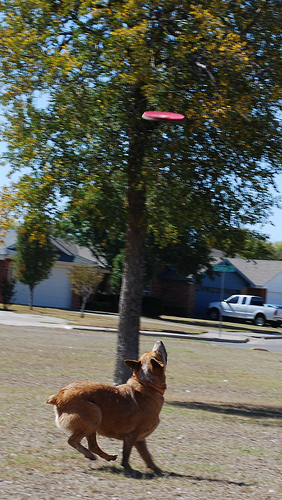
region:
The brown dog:
[42, 336, 168, 475]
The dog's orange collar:
[132, 376, 165, 394]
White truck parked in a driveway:
[209, 292, 280, 327]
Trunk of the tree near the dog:
[109, 91, 145, 391]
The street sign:
[211, 256, 239, 338]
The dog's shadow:
[88, 459, 258, 488]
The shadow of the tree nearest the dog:
[163, 396, 281, 425]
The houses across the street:
[0, 224, 281, 326]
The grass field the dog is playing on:
[1, 323, 281, 499]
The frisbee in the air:
[136, 108, 186, 128]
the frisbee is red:
[120, 89, 222, 151]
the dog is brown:
[14, 307, 254, 486]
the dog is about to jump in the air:
[25, 311, 222, 477]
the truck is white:
[211, 271, 279, 336]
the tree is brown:
[86, 120, 185, 433]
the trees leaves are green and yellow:
[1, 1, 278, 282]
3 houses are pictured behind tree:
[6, 218, 274, 344]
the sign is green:
[204, 257, 249, 286]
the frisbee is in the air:
[125, 91, 217, 155]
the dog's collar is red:
[128, 370, 191, 424]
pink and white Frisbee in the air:
[141, 109, 183, 117]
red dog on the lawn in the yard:
[43, 338, 164, 470]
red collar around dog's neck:
[130, 372, 161, 389]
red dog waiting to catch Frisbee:
[41, 107, 182, 472]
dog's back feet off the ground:
[61, 430, 112, 456]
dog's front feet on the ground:
[117, 440, 155, 469]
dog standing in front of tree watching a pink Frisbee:
[43, 108, 184, 473]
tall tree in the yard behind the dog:
[2, 0, 281, 475]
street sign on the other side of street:
[211, 259, 234, 335]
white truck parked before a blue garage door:
[209, 293, 280, 326]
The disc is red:
[133, 106, 197, 132]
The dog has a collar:
[41, 339, 194, 486]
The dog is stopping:
[43, 337, 186, 488]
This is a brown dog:
[52, 334, 201, 485]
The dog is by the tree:
[2, 3, 270, 413]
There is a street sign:
[212, 258, 239, 336]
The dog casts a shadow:
[51, 357, 258, 498]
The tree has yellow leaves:
[68, 263, 98, 320]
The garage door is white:
[17, 264, 83, 322]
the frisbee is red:
[108, 92, 221, 123]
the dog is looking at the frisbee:
[20, 340, 214, 486]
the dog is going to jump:
[26, 333, 213, 464]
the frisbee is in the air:
[119, 86, 204, 123]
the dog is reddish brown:
[31, 333, 179, 445]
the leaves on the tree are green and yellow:
[35, 10, 263, 168]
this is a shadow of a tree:
[170, 388, 276, 428]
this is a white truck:
[183, 277, 279, 325]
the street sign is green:
[183, 252, 241, 281]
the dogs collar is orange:
[112, 371, 171, 391]